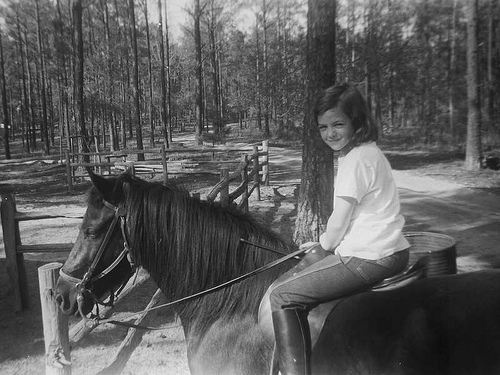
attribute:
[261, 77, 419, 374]
girl — riding english style, tween, horseback rider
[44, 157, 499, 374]
pony — darkly coloured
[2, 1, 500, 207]
area — wooded, for horseback riding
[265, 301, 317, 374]
boots — for horseback riding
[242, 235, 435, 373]
saddle — english style, leather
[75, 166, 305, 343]
mane — smooth, well-combed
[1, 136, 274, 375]
fence — wooden, low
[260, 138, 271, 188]
post — wooden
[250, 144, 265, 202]
post — wooden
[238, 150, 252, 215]
post — wooden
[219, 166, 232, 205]
post — wooden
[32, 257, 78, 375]
post — wooden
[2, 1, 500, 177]
trees — tall, in forest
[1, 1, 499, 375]
picture — outdoors, daytime, black, white, departed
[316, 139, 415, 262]
shirt — white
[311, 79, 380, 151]
hair — mid-length, shortish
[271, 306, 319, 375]
boot — black, left boot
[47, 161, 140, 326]
head — entire, actually in profile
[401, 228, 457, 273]
can — large, metal, barrel